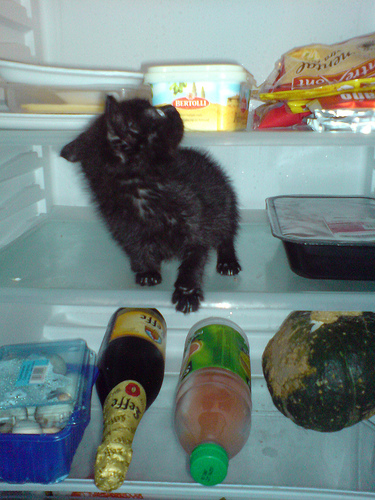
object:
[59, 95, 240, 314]
kitten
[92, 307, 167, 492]
bottle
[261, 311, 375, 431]
squash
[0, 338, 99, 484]
box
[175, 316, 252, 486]
bottle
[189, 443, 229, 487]
lid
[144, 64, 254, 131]
dish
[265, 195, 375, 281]
box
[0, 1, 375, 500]
fridge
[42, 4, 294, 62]
interior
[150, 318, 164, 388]
side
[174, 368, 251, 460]
juice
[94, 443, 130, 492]
seal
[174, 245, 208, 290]
legs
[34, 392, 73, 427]
mushrooms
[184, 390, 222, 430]
plastic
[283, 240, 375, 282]
lobster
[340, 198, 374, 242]
right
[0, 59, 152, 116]
container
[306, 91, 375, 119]
chips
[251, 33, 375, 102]
bag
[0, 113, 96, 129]
plate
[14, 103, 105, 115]
food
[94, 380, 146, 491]
foil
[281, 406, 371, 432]
bottom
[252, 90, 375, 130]
tortillas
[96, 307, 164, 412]
champagne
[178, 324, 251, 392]
green label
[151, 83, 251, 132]
butter